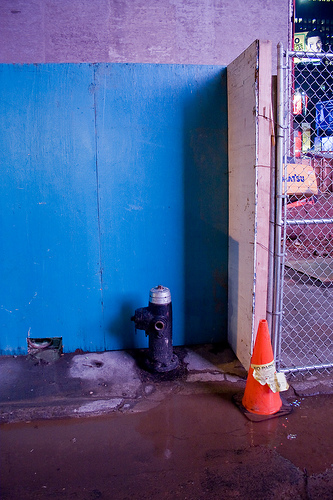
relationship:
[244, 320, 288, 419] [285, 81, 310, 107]
cone on ground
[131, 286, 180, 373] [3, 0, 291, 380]
fire hydrant by building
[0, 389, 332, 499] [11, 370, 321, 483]
water on ground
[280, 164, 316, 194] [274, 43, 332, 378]
box behind chain-link fencing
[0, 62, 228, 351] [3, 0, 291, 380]
blue wall on building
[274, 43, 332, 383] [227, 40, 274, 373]
chain-link fencing attached to a partial wall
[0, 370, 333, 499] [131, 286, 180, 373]
ground near fire hydrant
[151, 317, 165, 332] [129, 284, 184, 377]
nozzle on fire hydrant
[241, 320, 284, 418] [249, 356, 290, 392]
cone with torn paper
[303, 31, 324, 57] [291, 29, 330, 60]
man's face on a sign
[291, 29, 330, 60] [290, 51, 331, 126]
sign past fence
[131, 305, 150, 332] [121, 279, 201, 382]
nozzle on navy blue fire hydrant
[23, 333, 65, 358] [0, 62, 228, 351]
gap in blue wall